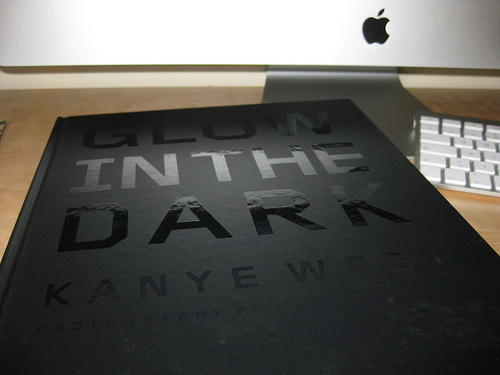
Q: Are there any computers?
A: Yes, there is a computer.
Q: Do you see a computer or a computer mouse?
A: Yes, there is a computer.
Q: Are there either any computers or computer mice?
A: Yes, there is a computer.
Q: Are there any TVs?
A: No, there are no tvs.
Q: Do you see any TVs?
A: No, there are no tvs.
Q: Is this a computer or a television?
A: This is a computer.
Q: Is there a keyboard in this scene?
A: Yes, there is a keyboard.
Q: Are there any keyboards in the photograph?
A: Yes, there is a keyboard.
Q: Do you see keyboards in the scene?
A: Yes, there is a keyboard.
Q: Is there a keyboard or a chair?
A: Yes, there is a keyboard.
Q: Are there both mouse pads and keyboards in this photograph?
A: No, there is a keyboard but no mouse pads.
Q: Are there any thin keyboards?
A: Yes, there is a thin keyboard.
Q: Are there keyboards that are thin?
A: Yes, there is a keyboard that is thin.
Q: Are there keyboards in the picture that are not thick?
A: Yes, there is a thin keyboard.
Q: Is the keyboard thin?
A: Yes, the keyboard is thin.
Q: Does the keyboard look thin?
A: Yes, the keyboard is thin.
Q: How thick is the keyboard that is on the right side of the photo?
A: The keyboard is thin.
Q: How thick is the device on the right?
A: The keyboard is thin.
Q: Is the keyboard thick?
A: No, the keyboard is thin.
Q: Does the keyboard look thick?
A: No, the keyboard is thin.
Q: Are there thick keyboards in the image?
A: No, there is a keyboard but it is thin.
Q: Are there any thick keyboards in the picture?
A: No, there is a keyboard but it is thin.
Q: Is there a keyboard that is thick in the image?
A: No, there is a keyboard but it is thin.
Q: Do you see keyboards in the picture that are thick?
A: No, there is a keyboard but it is thin.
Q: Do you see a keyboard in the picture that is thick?
A: No, there is a keyboard but it is thin.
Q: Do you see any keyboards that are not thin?
A: No, there is a keyboard but it is thin.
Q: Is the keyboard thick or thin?
A: The keyboard is thin.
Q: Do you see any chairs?
A: No, there are no chairs.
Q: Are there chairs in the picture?
A: No, there are no chairs.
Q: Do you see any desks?
A: Yes, there is a desk.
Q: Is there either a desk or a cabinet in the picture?
A: Yes, there is a desk.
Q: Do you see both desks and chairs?
A: No, there is a desk but no chairs.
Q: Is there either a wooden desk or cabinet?
A: Yes, there is a wood desk.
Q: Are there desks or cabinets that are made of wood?
A: Yes, the desk is made of wood.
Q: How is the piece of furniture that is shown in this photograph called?
A: The piece of furniture is a desk.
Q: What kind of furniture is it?
A: The piece of furniture is a desk.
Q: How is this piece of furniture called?
A: This is a desk.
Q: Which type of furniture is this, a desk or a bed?
A: This is a desk.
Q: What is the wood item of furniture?
A: The piece of furniture is a desk.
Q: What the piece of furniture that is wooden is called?
A: The piece of furniture is a desk.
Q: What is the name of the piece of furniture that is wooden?
A: The piece of furniture is a desk.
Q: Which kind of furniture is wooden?
A: The furniture is a desk.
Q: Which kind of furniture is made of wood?
A: The furniture is a desk.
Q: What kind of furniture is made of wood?
A: The furniture is a desk.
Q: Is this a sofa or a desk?
A: This is a desk.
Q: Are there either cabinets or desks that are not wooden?
A: No, there is a desk but it is wooden.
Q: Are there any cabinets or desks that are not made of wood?
A: No, there is a desk but it is made of wood.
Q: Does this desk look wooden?
A: Yes, the desk is wooden.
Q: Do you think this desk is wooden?
A: Yes, the desk is wooden.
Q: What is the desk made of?
A: The desk is made of wood.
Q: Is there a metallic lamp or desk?
A: No, there is a desk but it is wooden.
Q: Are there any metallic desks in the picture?
A: No, there is a desk but it is wooden.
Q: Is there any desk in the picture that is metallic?
A: No, there is a desk but it is wooden.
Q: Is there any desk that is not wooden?
A: No, there is a desk but it is wooden.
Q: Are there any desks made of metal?
A: No, there is a desk but it is made of wood.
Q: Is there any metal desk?
A: No, there is a desk but it is made of wood.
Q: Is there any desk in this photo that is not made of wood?
A: No, there is a desk but it is made of wood.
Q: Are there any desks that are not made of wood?
A: No, there is a desk but it is made of wood.